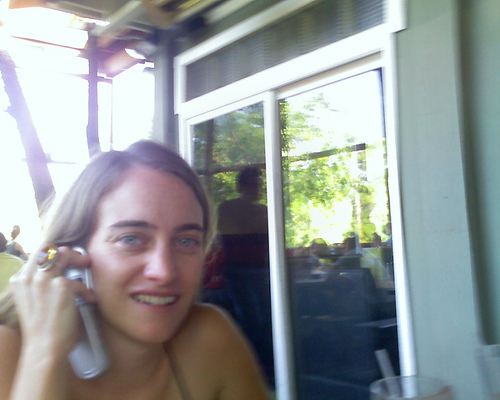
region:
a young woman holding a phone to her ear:
[0, 140, 270, 395]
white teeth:
[130, 290, 181, 301]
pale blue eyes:
[115, 230, 145, 246]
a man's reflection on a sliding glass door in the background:
[207, 155, 272, 255]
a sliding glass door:
[190, 47, 400, 397]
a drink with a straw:
[360, 340, 455, 395]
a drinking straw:
[371, 345, 396, 397]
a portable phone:
[49, 242, 104, 379]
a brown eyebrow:
[108, 216, 162, 231]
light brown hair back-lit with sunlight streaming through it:
[46, 181, 93, 238]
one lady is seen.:
[81, 179, 229, 371]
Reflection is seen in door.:
[210, 170, 385, 356]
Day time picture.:
[10, 105, 90, 165]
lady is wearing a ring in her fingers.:
[31, 245, 56, 277]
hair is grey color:
[61, 196, 91, 218]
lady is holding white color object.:
[53, 242, 124, 369]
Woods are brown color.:
[11, 98, 55, 184]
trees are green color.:
[226, 129, 349, 198]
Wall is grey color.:
[423, 175, 475, 266]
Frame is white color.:
[178, 96, 286, 158]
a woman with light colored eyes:
[35, 142, 230, 350]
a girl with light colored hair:
[18, 121, 254, 393]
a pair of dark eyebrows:
[107, 208, 212, 238]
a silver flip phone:
[43, 234, 120, 381]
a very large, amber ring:
[28, 236, 68, 285]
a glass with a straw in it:
[363, 332, 470, 398]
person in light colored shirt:
[0, 234, 37, 314]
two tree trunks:
[4, 51, 159, 244]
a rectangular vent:
[166, 0, 401, 121]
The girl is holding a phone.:
[4, 208, 128, 390]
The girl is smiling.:
[105, 275, 212, 330]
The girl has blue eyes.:
[105, 217, 213, 256]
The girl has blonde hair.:
[24, 130, 235, 247]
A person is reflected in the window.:
[201, 148, 281, 244]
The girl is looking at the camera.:
[60, 177, 247, 346]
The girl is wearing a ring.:
[25, 237, 63, 278]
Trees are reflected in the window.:
[270, 68, 393, 250]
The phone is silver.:
[50, 240, 117, 385]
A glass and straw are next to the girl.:
[355, 340, 460, 398]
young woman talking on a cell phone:
[6, 21, 492, 396]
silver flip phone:
[46, 231, 115, 387]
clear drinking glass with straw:
[360, 348, 456, 394]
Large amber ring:
[35, 236, 64, 276]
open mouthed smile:
[126, 283, 193, 332]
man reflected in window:
[212, 158, 282, 273]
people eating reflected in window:
[298, 204, 413, 306]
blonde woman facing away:
[0, 216, 30, 261]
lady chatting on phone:
[15, 131, 285, 395]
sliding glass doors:
[174, 52, 435, 398]